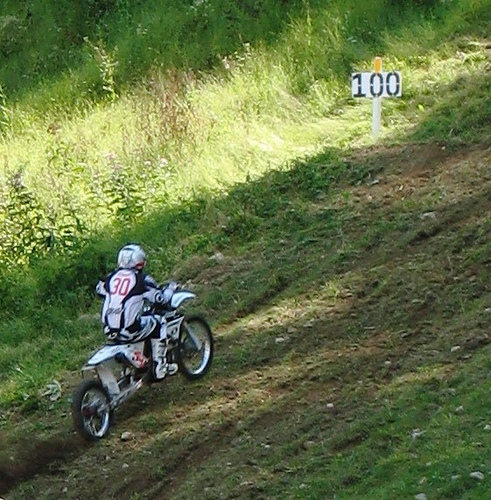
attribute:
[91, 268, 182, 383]
outfit — white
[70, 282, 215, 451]
motorcycle — white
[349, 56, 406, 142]
sign — white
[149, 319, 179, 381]
boot — silver, white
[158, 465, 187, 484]
dirt — brown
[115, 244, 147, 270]
helmet color — grey, white, silver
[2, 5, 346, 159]
grass — green, tall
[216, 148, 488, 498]
ground — brown, green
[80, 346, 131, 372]
motorcycle fender — white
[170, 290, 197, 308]
motorcycle fender — white